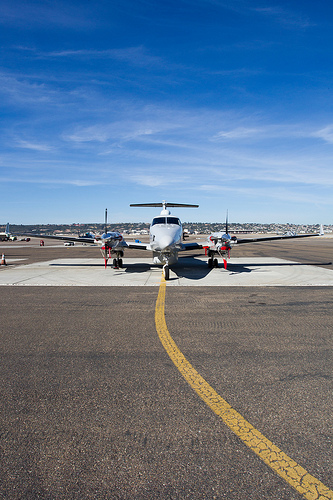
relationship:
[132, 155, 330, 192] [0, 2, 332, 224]
clouds in sky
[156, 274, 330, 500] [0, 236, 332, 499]
line on ground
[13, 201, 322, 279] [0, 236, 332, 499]
plane on ground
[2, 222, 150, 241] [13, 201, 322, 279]
hill behind plane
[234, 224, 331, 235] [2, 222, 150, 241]
houses on hill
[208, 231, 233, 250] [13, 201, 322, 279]
engine on plane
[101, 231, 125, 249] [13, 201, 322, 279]
engine on plane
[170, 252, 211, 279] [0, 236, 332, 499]
shadow on ground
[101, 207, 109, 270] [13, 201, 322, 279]
propeller on plane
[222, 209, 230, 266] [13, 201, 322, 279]
propeller on plane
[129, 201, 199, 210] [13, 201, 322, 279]
tail of plane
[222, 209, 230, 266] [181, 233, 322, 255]
propeller on wing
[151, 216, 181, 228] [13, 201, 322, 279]
window on plane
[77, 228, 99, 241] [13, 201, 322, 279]
helicopter behind plane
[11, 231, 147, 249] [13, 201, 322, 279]
wing on plane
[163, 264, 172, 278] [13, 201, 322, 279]
wheel on plane